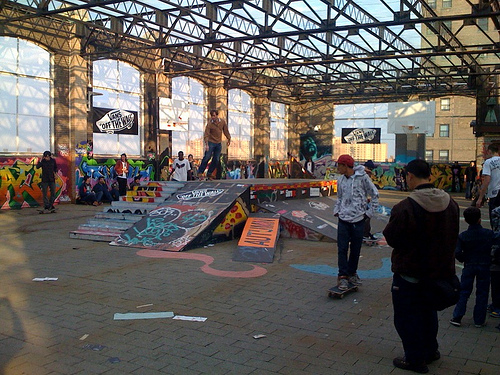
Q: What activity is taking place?
A: Skateboarding.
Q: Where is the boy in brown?
A: On ramp.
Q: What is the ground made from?
A: Bricks.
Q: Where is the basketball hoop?
A: Hanging at back near high rise.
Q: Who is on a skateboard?
A: A boy.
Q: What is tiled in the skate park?
A: The floors.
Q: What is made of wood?
A: Ramps.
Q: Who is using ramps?
A: Three skaters.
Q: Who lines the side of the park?
A: Spectators.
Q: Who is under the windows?
A: Spectators.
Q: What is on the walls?
A: Graffiti.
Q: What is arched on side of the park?
A: The windows.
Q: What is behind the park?
A: Buildings.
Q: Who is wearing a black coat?
A: A man.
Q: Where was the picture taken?
A: In a skate park.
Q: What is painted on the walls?
A: Graffiti.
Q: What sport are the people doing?
A: Skateboarding.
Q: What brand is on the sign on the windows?
A: VANS.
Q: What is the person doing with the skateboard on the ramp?
A: A trick.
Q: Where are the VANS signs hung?
A: On windows.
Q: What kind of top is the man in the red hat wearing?
A: A hoodie.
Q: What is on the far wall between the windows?
A: A basketball net.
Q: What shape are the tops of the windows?
A: Arched.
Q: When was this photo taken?
A: During the day.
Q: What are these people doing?
A: Skateboarding.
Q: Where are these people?
A: At a skate park.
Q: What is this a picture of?
A: People skateboarding.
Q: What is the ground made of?
A: Cobblestone.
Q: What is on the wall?
A: Graffiti.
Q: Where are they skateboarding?
A: At a skateboard park.